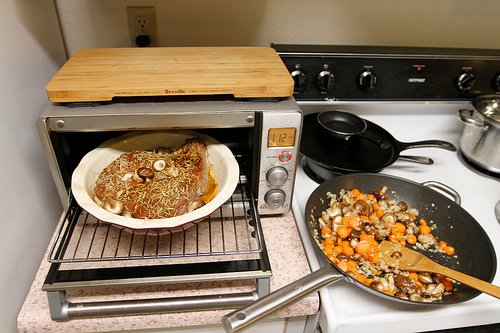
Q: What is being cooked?
A: Food.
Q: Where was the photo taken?
A: In the kitchen.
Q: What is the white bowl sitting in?
A: A toaster oven.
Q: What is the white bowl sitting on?
A: A silver rack.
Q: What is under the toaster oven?
A: A counter top.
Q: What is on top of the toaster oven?
A: A wooden cutting board.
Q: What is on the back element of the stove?
A: A cast iron skillet.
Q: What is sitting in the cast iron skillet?
A: A small pot.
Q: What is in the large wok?
A: Stir fried vegetables.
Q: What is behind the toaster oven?
A: A wall with an electrical outlet.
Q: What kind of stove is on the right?
A: An electric stove.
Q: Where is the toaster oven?
A: On the counter next to the stove.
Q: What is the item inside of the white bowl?
A: It is a mixture of foods.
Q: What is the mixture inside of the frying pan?
A: It is an assortment of foods.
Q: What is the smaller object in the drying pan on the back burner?
A: It is a small black pot.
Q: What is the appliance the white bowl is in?
A: It is a small oven.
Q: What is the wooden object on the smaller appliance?
A: It is a small wooden cutting board.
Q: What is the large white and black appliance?
A: It is a stove top oven.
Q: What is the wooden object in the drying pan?
A: It is a wooden spoon.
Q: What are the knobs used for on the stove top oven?
A: They are top adjust the temperature.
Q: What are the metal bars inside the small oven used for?
A: They are a rack used to hold food items.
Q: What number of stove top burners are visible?
A: Three stove top burners are visible in this picture.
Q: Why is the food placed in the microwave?
A: To warm.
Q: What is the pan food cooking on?
A: A stove.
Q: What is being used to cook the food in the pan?
A: A wooden spoon.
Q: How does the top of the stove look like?
A: White and spotless.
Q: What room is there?
A: Kitchen.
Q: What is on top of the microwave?
A: Tray.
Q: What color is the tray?
A: Brown.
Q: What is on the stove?
A: Pan.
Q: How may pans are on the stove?
A: Two.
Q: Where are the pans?
A: Stove.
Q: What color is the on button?
A: Red.